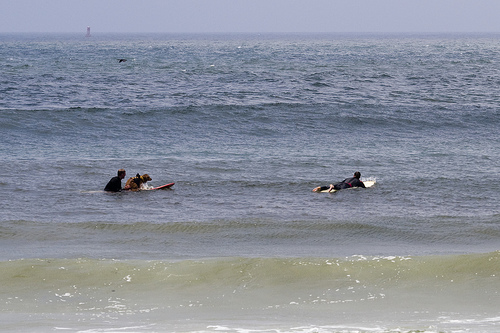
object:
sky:
[0, 1, 499, 39]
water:
[160, 77, 286, 133]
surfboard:
[321, 178, 376, 194]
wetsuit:
[320, 178, 370, 190]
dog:
[123, 172, 144, 191]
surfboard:
[137, 179, 175, 192]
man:
[310, 169, 368, 193]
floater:
[84, 25, 92, 37]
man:
[102, 169, 127, 192]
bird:
[111, 56, 129, 66]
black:
[104, 175, 123, 194]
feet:
[309, 182, 324, 193]